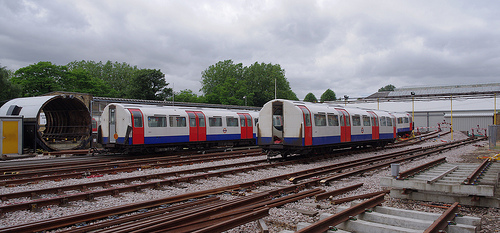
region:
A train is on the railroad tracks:
[95, 33, 483, 230]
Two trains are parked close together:
[90, 31, 470, 228]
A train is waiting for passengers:
[95, 6, 470, 221]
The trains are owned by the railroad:
[86, 16, 461, 227]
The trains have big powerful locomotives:
[92, 33, 478, 230]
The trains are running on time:
[98, 61, 454, 231]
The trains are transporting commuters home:
[100, 25, 470, 215]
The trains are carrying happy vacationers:
[96, 30, 486, 230]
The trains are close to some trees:
[95, 36, 471, 231]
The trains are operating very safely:
[100, 5, 462, 217]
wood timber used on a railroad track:
[378, 207, 415, 221]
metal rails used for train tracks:
[209, 205, 244, 221]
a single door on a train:
[127, 103, 147, 146]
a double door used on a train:
[184, 108, 209, 148]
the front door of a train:
[265, 100, 290, 148]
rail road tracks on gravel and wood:
[85, 174, 151, 195]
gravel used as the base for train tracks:
[369, 178, 382, 189]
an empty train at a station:
[259, 91, 420, 161]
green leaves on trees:
[216, 68, 265, 91]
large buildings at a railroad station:
[378, 83, 498, 126]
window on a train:
[301, 109, 314, 125]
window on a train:
[315, 110, 327, 125]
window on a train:
[326, 112, 338, 124]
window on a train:
[340, 112, 350, 124]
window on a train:
[349, 112, 361, 127]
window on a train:
[361, 114, 372, 128]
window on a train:
[148, 113, 170, 128]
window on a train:
[166, 113, 188, 126]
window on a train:
[206, 115, 223, 127]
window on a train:
[226, 116, 240, 129]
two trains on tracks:
[95, 94, 412, 162]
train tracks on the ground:
[15, 116, 484, 231]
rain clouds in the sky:
[0, 5, 489, 89]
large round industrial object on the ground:
[0, 96, 92, 156]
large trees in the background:
[0, 55, 355, 98]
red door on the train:
[125, 102, 145, 148]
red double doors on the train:
[183, 106, 211, 147]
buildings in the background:
[365, 88, 494, 140]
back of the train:
[256, 100, 304, 150]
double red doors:
[234, 108, 256, 143]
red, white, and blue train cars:
[268, 95, 417, 145]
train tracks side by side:
[44, 153, 291, 218]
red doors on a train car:
[184, 108, 209, 140]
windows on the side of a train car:
[312, 110, 342, 129]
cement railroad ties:
[360, 206, 435, 231]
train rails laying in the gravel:
[313, 174, 385, 204]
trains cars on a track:
[257, 93, 420, 163]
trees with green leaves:
[50, 64, 140, 90]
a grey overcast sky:
[2, 1, 492, 98]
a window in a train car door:
[133, 110, 143, 127]